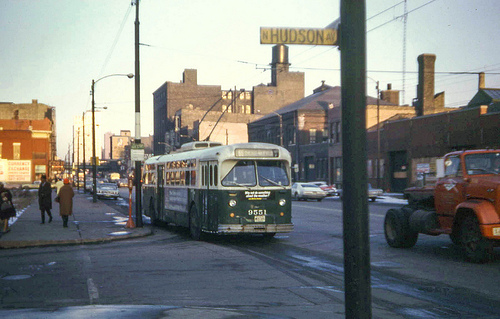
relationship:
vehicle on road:
[382, 146, 500, 264] [195, 173, 434, 319]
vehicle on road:
[382, 146, 500, 264] [244, 200, 401, 302]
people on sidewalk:
[24, 166, 84, 213] [15, 210, 159, 272]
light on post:
[56, 60, 113, 188] [100, 62, 153, 81]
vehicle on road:
[282, 174, 319, 195] [235, 204, 355, 299]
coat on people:
[25, 180, 61, 204] [36, 174, 54, 223]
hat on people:
[50, 180, 86, 186] [36, 174, 54, 223]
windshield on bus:
[148, 130, 325, 258] [202, 150, 311, 185]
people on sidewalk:
[36, 174, 54, 223] [29, 216, 159, 253]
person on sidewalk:
[28, 164, 82, 210] [12, 224, 170, 259]